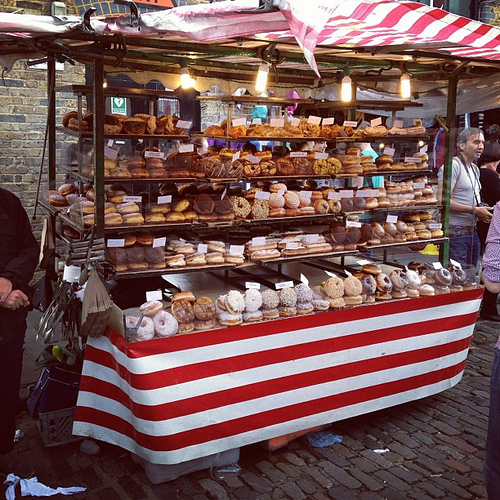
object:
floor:
[0, 316, 498, 498]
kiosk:
[39, 4, 500, 484]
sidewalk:
[3, 273, 495, 500]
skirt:
[74, 284, 484, 466]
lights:
[176, 73, 197, 93]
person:
[0, 185, 41, 498]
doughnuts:
[189, 195, 216, 214]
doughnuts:
[225, 288, 248, 313]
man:
[438, 125, 495, 284]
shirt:
[434, 158, 484, 236]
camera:
[477, 201, 493, 220]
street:
[0, 261, 494, 500]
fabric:
[139, 1, 498, 61]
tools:
[36, 256, 69, 343]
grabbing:
[34, 261, 81, 346]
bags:
[79, 266, 114, 337]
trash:
[307, 431, 340, 448]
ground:
[0, 413, 500, 500]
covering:
[1, 0, 499, 65]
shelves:
[100, 113, 451, 277]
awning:
[0, 1, 499, 73]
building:
[0, 1, 500, 285]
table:
[85, 255, 476, 340]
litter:
[22, 479, 51, 496]